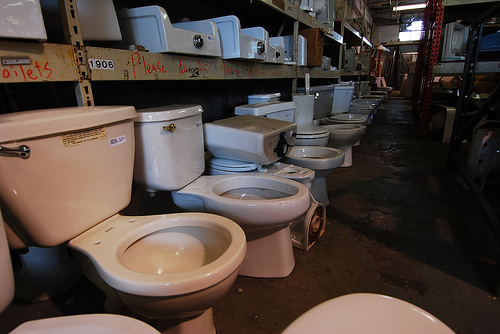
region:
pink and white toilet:
[2, 88, 248, 331]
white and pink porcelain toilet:
[5, 101, 252, 330]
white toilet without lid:
[135, 98, 322, 291]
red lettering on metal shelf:
[127, 49, 298, 85]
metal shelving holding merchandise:
[2, 3, 383, 110]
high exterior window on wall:
[393, 14, 430, 51]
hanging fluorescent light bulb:
[390, 3, 432, 14]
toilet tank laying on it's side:
[200, 104, 302, 171]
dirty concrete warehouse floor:
[0, 91, 495, 331]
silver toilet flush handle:
[2, 142, 32, 164]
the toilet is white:
[152, 113, 277, 248]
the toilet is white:
[247, 94, 342, 205]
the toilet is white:
[145, 95, 350, 310]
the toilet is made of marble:
[147, 96, 291, 286]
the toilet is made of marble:
[269, 98, 353, 195]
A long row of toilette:
[3, 75, 363, 307]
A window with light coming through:
[395, 15, 423, 47]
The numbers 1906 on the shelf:
[82, 55, 122, 75]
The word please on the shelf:
[125, 48, 171, 80]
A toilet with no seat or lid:
[0, 95, 245, 331]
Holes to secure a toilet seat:
[89, 211, 140, 256]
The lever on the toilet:
[156, 122, 180, 132]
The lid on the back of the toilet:
[131, 102, 202, 126]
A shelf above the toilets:
[2, 40, 366, 85]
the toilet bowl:
[99, 212, 250, 302]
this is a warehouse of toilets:
[16, 10, 452, 316]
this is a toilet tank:
[10, 100, 150, 255]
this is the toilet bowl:
[201, 169, 308, 231]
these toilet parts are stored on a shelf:
[93, 2, 315, 82]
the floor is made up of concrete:
[341, 95, 474, 331]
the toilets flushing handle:
[0, 136, 42, 173]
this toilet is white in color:
[152, 101, 306, 272]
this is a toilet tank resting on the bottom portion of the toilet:
[212, 105, 302, 168]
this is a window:
[393, 10, 424, 44]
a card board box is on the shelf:
[285, 16, 333, 68]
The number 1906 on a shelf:
[86, 56, 116, 72]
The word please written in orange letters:
[128, 51, 171, 76]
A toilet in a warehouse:
[1, 113, 244, 304]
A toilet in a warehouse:
[136, 101, 305, 278]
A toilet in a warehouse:
[203, 110, 315, 185]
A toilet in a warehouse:
[234, 95, 348, 189]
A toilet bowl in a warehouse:
[295, 121, 330, 145]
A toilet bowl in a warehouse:
[325, 123, 375, 165]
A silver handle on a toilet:
[1, 145, 33, 157]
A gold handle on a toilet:
[157, 123, 179, 131]